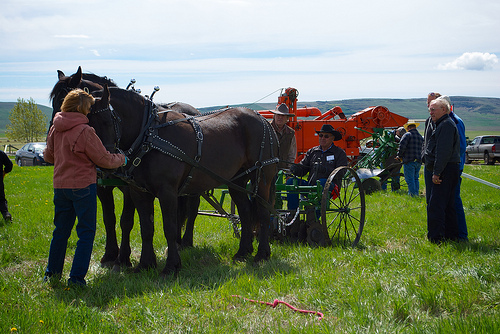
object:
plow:
[279, 212, 334, 247]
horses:
[49, 65, 281, 283]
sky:
[2, 3, 497, 109]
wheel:
[316, 165, 368, 246]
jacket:
[40, 114, 125, 189]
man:
[286, 124, 349, 236]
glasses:
[316, 133, 331, 139]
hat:
[314, 123, 343, 141]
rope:
[216, 289, 323, 321]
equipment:
[256, 86, 408, 172]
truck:
[460, 133, 499, 166]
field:
[0, 167, 498, 334]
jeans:
[42, 182, 99, 281]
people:
[417, 98, 460, 243]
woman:
[42, 89, 126, 288]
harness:
[125, 109, 148, 176]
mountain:
[0, 101, 54, 135]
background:
[3, 1, 494, 333]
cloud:
[0, 0, 499, 107]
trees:
[5, 96, 48, 143]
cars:
[14, 140, 54, 170]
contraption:
[194, 162, 366, 249]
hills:
[0, 96, 499, 136]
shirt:
[396, 130, 425, 165]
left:
[8, 3, 52, 330]